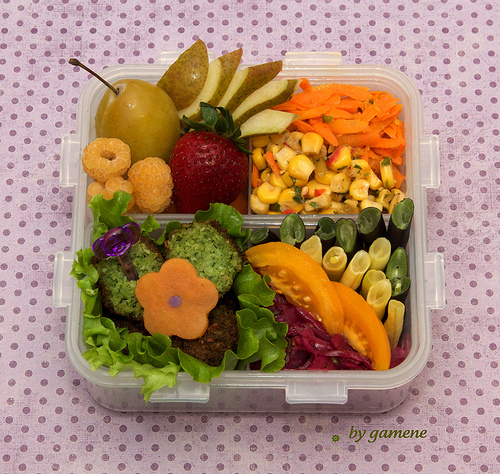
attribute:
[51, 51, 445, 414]
container — clear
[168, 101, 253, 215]
strawberry — red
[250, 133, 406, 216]
corn — yellow, marinated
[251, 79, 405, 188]
carrots — shredded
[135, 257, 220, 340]
melon — orange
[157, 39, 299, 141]
pear — sliced, green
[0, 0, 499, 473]
table — polkadotted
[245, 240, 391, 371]
tomato — sliced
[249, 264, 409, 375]
beets — shredded, magenta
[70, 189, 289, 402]
lettuce — green